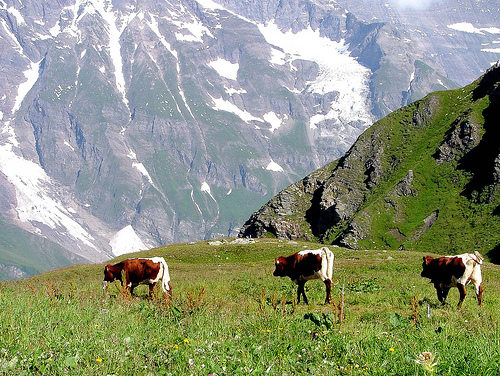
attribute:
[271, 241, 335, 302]
cow — white, Brown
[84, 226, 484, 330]
cows — Three, walking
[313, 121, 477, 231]
hill — rocky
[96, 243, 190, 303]
cow — ear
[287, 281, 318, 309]
cow —  front legs 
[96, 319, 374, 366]
grass — white flower 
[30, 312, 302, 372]
field — green grassy  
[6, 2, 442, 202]
mountain — white snow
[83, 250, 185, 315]
cow —  tail 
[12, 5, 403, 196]
mountain — filled, snowy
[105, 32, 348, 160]
mountain — snowy, filled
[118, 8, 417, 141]
mountain — snowy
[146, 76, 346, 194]
mountain — snowy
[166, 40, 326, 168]
mountains — snowcapped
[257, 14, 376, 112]
mountains — snowy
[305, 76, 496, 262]
mountains — closest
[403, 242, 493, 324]
cow — third, facing left